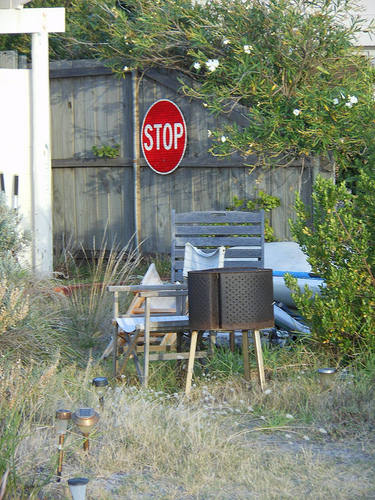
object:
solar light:
[71, 407, 102, 463]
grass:
[100, 407, 242, 472]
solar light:
[54, 407, 73, 484]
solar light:
[94, 377, 109, 407]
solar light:
[63, 476, 92, 500]